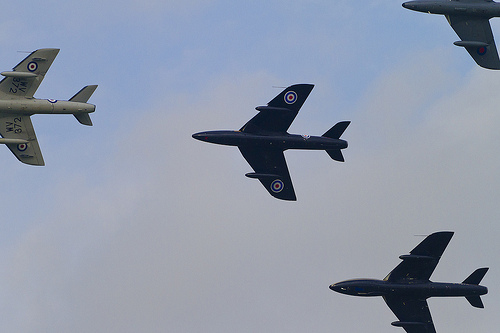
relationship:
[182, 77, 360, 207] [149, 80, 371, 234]
jet in middle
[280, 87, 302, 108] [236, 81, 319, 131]
bullseye on wing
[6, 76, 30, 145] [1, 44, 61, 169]
jet under wings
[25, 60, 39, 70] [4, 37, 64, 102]
red dot under wing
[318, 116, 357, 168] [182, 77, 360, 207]
tail of fighter jet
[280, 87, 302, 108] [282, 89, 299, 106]
circle has bullseye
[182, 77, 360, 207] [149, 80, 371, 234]
plane in center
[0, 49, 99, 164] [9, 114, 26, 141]
jet number 372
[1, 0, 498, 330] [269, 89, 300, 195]
jets have bullseyes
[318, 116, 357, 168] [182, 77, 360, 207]
tail of jet fighter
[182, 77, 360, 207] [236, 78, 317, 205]
jet has wings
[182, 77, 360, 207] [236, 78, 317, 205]
jet wings are swept back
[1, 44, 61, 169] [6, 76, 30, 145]
wings has writing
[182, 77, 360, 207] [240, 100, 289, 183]
jet has two fuel tanks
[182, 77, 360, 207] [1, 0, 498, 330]
blue plane in sky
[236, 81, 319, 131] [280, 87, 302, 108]
wing has a target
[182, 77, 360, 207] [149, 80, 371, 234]
plane in middle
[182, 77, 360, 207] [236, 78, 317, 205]
plane has wings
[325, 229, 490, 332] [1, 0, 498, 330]
jet in sky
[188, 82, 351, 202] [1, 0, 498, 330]
jet in sky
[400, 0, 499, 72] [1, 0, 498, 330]
jet in sky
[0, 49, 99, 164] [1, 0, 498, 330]
jet in sky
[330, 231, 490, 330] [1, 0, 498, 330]
jet in sky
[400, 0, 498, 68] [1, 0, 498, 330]
jet in sky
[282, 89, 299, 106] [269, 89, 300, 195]
bullseye on wings